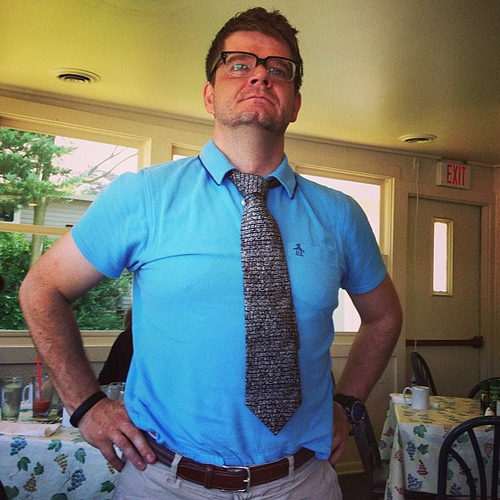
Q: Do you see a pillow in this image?
A: No, there are no pillows.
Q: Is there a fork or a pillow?
A: No, there are no pillows or forks.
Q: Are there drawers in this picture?
A: No, there are no drawers.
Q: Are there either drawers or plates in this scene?
A: No, there are no drawers or plates.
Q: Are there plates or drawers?
A: No, there are no drawers or plates.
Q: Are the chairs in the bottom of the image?
A: Yes, the chairs are in the bottom of the image.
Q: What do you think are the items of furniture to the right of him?
A: The pieces of furniture are chairs.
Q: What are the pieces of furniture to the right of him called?
A: The pieces of furniture are chairs.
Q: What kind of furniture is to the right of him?
A: The pieces of furniture are chairs.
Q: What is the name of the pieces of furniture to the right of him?
A: The pieces of furniture are chairs.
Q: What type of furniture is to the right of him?
A: The pieces of furniture are chairs.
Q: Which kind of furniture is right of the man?
A: The pieces of furniture are chairs.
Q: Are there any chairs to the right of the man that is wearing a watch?
A: Yes, there are chairs to the right of the man.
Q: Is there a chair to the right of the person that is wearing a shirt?
A: Yes, there are chairs to the right of the man.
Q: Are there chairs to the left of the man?
A: No, the chairs are to the right of the man.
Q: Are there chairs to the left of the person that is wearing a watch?
A: No, the chairs are to the right of the man.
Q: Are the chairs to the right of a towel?
A: No, the chairs are to the right of the man.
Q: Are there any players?
A: No, there are no players.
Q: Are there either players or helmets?
A: No, there are no players or helmets.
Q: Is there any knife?
A: No, there are no knives.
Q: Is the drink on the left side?
A: Yes, the drink is on the left of the image.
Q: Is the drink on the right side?
A: No, the drink is on the left of the image.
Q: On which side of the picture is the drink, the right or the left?
A: The drink is on the left of the image.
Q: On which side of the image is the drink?
A: The drink is on the left of the image.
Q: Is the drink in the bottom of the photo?
A: Yes, the drink is in the bottom of the image.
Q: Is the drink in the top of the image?
A: No, the drink is in the bottom of the image.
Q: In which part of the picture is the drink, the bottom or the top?
A: The drink is in the bottom of the image.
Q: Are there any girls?
A: No, there are no girls.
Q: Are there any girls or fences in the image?
A: No, there are no girls or fences.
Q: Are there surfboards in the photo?
A: No, there are no surfboards.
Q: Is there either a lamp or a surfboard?
A: No, there are no surfboards or lamps.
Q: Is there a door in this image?
A: Yes, there is a door.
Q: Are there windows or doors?
A: Yes, there is a door.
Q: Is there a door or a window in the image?
A: Yes, there is a door.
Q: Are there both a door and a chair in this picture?
A: Yes, there are both a door and a chair.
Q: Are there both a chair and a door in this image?
A: Yes, there are both a door and a chair.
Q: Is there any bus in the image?
A: No, there are no buses.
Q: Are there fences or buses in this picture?
A: No, there are no buses or fences.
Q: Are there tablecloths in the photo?
A: Yes, there is a tablecloth.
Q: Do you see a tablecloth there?
A: Yes, there is a tablecloth.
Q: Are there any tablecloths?
A: Yes, there is a tablecloth.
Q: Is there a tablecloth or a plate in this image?
A: Yes, there is a tablecloth.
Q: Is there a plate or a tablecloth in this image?
A: Yes, there is a tablecloth.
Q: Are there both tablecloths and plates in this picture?
A: No, there is a tablecloth but no plates.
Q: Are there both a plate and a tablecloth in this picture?
A: No, there is a tablecloth but no plates.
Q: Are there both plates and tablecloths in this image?
A: No, there is a tablecloth but no plates.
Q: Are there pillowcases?
A: No, there are no pillowcases.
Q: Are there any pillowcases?
A: No, there are no pillowcases.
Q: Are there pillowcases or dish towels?
A: No, there are no pillowcases or dish towels.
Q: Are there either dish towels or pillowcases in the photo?
A: No, there are no pillowcases or dish towels.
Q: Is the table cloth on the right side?
A: Yes, the table cloth is on the right of the image.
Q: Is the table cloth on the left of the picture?
A: No, the table cloth is on the right of the image.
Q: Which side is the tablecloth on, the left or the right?
A: The tablecloth is on the right of the image.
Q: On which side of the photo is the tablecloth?
A: The tablecloth is on the right of the image.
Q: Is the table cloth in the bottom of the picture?
A: Yes, the table cloth is in the bottom of the image.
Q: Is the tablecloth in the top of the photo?
A: No, the tablecloth is in the bottom of the image.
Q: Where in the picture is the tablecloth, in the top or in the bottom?
A: The tablecloth is in the bottom of the image.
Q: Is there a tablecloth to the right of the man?
A: Yes, there is a tablecloth to the right of the man.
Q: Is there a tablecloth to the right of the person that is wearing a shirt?
A: Yes, there is a tablecloth to the right of the man.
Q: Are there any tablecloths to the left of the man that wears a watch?
A: No, the tablecloth is to the right of the man.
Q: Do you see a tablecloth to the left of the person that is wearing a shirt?
A: No, the tablecloth is to the right of the man.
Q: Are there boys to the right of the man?
A: No, there is a tablecloth to the right of the man.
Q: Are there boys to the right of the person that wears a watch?
A: No, there is a tablecloth to the right of the man.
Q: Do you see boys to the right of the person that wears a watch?
A: No, there is a tablecloth to the right of the man.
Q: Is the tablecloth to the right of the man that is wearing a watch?
A: Yes, the tablecloth is to the right of the man.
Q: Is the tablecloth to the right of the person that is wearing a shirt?
A: Yes, the tablecloth is to the right of the man.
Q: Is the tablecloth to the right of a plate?
A: No, the tablecloth is to the right of the man.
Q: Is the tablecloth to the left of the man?
A: No, the tablecloth is to the right of the man.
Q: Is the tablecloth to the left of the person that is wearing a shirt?
A: No, the tablecloth is to the right of the man.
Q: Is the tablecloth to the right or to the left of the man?
A: The tablecloth is to the right of the man.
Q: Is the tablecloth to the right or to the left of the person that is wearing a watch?
A: The tablecloth is to the right of the man.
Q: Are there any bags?
A: No, there are no bags.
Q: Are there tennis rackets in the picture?
A: No, there are no tennis rackets.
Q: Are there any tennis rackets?
A: No, there are no tennis rackets.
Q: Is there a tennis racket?
A: No, there are no rackets.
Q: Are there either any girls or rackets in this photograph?
A: No, there are no rackets or girls.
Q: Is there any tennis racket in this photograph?
A: No, there are no rackets.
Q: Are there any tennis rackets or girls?
A: No, there are no tennis rackets or girls.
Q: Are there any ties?
A: Yes, there is a tie.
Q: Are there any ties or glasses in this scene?
A: Yes, there is a tie.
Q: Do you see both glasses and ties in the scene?
A: Yes, there are both a tie and glasses.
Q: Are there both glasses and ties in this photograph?
A: Yes, there are both a tie and glasses.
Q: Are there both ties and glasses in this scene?
A: Yes, there are both a tie and glasses.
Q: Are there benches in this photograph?
A: No, there are no benches.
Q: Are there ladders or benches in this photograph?
A: No, there are no benches or ladders.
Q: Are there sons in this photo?
A: No, there are no sons.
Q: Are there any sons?
A: No, there are no sons.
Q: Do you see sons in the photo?
A: No, there are no sons.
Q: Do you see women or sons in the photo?
A: No, there are no sons or women.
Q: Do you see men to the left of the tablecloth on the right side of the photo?
A: Yes, there is a man to the left of the tablecloth.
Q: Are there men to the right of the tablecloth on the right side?
A: No, the man is to the left of the tablecloth.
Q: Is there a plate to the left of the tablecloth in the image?
A: No, there is a man to the left of the tablecloth.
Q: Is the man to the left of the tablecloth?
A: Yes, the man is to the left of the tablecloth.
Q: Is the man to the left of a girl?
A: No, the man is to the left of the tablecloth.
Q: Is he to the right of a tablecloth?
A: No, the man is to the left of a tablecloth.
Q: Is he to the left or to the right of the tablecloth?
A: The man is to the left of the tablecloth.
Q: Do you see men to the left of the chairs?
A: Yes, there is a man to the left of the chairs.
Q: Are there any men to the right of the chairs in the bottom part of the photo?
A: No, the man is to the left of the chairs.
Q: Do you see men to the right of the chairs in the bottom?
A: No, the man is to the left of the chairs.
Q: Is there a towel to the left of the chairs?
A: No, there is a man to the left of the chairs.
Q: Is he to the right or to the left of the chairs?
A: The man is to the left of the chairs.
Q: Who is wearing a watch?
A: The man is wearing a watch.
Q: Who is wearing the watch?
A: The man is wearing a watch.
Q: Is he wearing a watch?
A: Yes, the man is wearing a watch.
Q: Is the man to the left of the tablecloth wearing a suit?
A: No, the man is wearing a watch.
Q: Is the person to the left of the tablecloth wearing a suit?
A: No, the man is wearing a watch.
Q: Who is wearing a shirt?
A: The man is wearing a shirt.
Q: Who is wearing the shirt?
A: The man is wearing a shirt.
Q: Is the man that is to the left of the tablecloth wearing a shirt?
A: Yes, the man is wearing a shirt.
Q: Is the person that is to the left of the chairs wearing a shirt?
A: Yes, the man is wearing a shirt.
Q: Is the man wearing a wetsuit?
A: No, the man is wearing a shirt.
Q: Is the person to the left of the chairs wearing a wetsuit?
A: No, the man is wearing a shirt.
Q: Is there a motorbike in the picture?
A: No, there are no motorcycles.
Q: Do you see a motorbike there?
A: No, there are no motorcycles.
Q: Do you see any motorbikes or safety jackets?
A: No, there are no motorbikes or safety jackets.